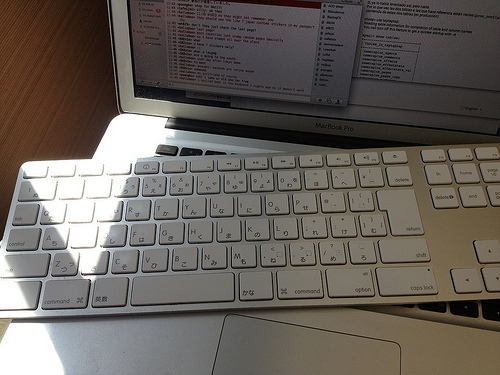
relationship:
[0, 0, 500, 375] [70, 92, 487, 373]
computer on table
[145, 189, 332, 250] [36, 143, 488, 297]
letters on keyboard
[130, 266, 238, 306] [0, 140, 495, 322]
spacebar on keypad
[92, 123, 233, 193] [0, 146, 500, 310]
buttons on buttons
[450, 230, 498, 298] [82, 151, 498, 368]
buttons on keyboard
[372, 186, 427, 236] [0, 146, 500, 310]
button on buttons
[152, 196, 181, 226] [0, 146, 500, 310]
key on buttons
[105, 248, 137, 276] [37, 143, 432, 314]
key on keyboard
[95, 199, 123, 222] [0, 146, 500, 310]
key on buttons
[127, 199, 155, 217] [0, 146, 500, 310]
white on buttons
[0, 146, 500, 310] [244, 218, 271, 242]
buttons has key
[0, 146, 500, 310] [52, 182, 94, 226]
buttons has key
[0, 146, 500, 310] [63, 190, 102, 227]
buttons has key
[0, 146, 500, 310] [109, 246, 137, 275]
buttons has key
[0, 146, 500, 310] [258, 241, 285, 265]
buttons has key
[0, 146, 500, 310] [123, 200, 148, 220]
buttons has key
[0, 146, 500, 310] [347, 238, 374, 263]
buttons has key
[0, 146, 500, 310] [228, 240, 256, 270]
buttons has letter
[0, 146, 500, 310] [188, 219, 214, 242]
buttons has white letter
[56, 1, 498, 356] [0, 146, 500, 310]
computer has buttons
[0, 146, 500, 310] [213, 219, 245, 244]
buttons has letter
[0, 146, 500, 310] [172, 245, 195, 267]
buttons has letter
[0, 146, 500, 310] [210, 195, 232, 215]
buttons has letter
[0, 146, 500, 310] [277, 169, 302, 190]
buttons has letter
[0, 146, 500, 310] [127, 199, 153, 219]
buttons has letter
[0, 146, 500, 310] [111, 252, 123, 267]
buttons has letter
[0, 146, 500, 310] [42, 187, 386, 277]
buttons has letters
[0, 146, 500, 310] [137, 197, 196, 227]
buttons has letter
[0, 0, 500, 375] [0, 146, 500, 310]
computer has buttons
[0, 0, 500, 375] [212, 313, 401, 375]
computer has mousepad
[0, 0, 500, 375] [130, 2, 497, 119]
computer has monitor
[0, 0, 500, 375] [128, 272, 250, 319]
computer has spacebar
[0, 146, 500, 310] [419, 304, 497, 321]
buttons has buttons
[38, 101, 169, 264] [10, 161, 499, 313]
light reflection on keyboard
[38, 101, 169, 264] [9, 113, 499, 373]
light reflection on keyboard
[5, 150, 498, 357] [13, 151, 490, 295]
shadow on buttons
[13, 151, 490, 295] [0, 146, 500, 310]
buttons on buttons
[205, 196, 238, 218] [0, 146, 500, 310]
key on buttons